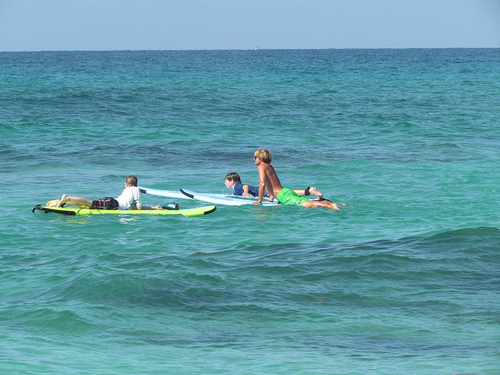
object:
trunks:
[276, 188, 313, 208]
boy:
[45, 175, 162, 212]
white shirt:
[115, 186, 141, 210]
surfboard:
[179, 185, 280, 208]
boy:
[223, 173, 324, 198]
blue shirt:
[234, 182, 260, 196]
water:
[6, 63, 500, 359]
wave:
[16, 218, 500, 337]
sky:
[2, 2, 500, 50]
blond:
[250, 144, 342, 211]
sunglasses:
[254, 155, 262, 160]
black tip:
[179, 188, 194, 199]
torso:
[258, 167, 280, 192]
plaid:
[94, 199, 114, 209]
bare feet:
[328, 202, 340, 211]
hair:
[252, 149, 273, 163]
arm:
[257, 167, 267, 205]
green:
[103, 210, 187, 214]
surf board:
[138, 186, 262, 203]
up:
[252, 144, 277, 208]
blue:
[236, 184, 243, 194]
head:
[224, 172, 242, 189]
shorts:
[89, 198, 118, 210]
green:
[281, 190, 300, 203]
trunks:
[90, 195, 123, 213]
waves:
[6, 129, 500, 272]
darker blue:
[1, 49, 499, 72]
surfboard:
[51, 190, 210, 231]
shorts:
[275, 187, 309, 207]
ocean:
[293, 100, 453, 274]